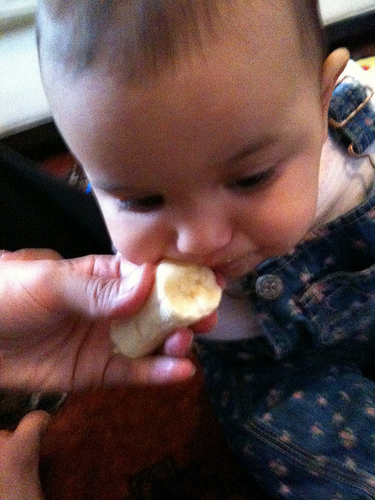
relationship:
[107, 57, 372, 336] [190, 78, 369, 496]
shirt under overalls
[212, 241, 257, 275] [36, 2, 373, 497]
mouth of baby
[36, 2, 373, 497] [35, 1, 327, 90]
baby has hair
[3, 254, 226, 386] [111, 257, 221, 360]
hand holding banana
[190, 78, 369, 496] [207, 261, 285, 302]
overalls have clasp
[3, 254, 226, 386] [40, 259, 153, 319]
hand with thumb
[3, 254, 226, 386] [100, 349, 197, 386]
hand with finger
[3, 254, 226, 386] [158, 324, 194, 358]
hand with finger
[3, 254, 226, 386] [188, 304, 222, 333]
hand with finger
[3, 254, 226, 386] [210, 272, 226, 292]
hand with finger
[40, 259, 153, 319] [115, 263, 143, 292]
thumb with thumbnail